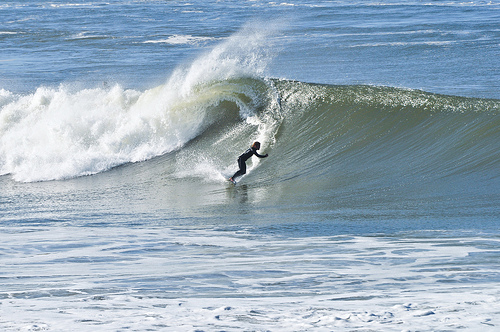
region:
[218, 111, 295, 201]
a surfer riding a wave.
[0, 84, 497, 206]
a wave in the ocean.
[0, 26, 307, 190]
foam created by a wave.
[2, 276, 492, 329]
a foamy section of water.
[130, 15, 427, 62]
a wave out in the ocean.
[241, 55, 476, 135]
a section of a wave top.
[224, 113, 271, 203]
a person riding a surfboard.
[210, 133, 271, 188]
a person in a wet suit.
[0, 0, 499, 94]
a large body of ocean water.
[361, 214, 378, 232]
part of a water body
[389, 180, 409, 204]
part of a wave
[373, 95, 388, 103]
top of a wave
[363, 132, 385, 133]
middle of a wave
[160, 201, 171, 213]
ripples of ocean water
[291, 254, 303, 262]
part of the ocean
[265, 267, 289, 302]
part of the lake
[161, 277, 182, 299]
part of the sea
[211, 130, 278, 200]
a surfer who has caught a wave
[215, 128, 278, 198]
a surfer wearing a wet suit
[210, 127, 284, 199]
a person on a surfboard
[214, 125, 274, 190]
a surfer with bent knees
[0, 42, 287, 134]
a wave breaking behind the surfer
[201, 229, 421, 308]
foam on the water surface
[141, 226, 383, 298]
foam on the surface of the water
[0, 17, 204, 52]
white caps behind the big wave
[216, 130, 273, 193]
surfer leaning into the wave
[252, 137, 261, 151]
the head of a surfer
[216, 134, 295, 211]
surfer in black wetsuit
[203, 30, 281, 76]
white water of waves splashing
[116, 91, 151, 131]
white water of waves splashing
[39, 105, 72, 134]
white water of waves splashing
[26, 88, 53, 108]
white water of waves splashing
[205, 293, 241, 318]
white water of waves splashing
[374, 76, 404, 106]
white water of waves splashing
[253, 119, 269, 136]
white water of waves splashing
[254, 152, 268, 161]
arms of surfer outstretched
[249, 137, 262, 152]
head of surfer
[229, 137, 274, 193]
distant surfer on wave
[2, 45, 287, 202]
ocean white cap curling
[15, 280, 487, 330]
thick white sea foam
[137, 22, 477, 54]
distant ocean white caps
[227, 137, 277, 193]
black surfer wet suit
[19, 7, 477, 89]
calm distant ocean water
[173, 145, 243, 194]
splash thrown from surf board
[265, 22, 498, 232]
greenish brown ocean water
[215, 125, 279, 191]
surfer leaning forward for balance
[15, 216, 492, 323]
calm foreground ocean water